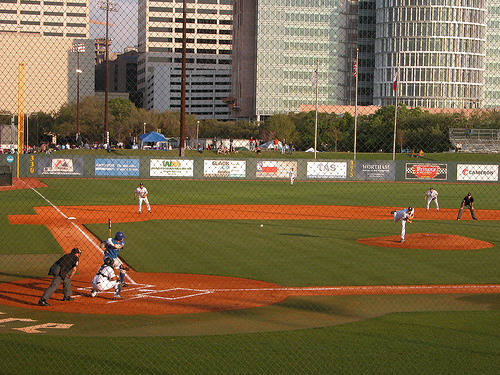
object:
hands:
[456, 202, 477, 209]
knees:
[457, 207, 481, 214]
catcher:
[88, 257, 131, 302]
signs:
[34, 157, 497, 184]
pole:
[333, 44, 384, 171]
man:
[33, 243, 83, 306]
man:
[454, 187, 484, 224]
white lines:
[73, 279, 213, 305]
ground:
[438, 143, 477, 183]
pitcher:
[385, 195, 420, 245]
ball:
[252, 210, 274, 232]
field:
[0, 14, 467, 373]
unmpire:
[39, 246, 79, 303]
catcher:
[91, 257, 118, 297]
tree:
[260, 113, 298, 145]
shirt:
[55, 254, 79, 264]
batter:
[91, 213, 145, 278]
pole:
[66, 31, 91, 106]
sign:
[35, 154, 85, 177]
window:
[282, 25, 288, 37]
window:
[318, 27, 325, 39]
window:
[320, 82, 327, 92]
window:
[282, 85, 287, 93]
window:
[312, 10, 319, 22]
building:
[236, 0, 356, 117]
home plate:
[140, 285, 155, 292]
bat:
[86, 212, 119, 232]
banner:
[146, 161, 206, 184]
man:
[100, 233, 128, 290]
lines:
[129, 274, 347, 301]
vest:
[46, 253, 79, 280]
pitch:
[257, 220, 267, 230]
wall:
[18, 155, 498, 181]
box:
[71, 274, 153, 293]